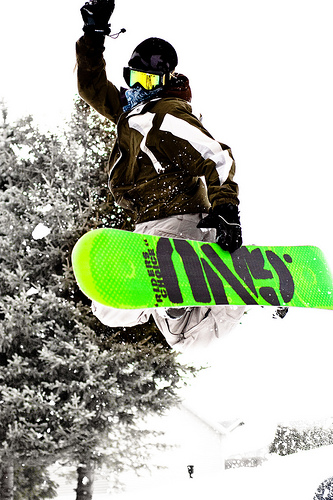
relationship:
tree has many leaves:
[1, 83, 223, 500] [2, 83, 193, 498]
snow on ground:
[107, 440, 332, 499] [52, 446, 331, 499]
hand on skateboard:
[204, 203, 243, 256] [70, 224, 333, 312]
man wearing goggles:
[54, 5, 292, 347] [119, 63, 171, 98]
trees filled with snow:
[1, 83, 223, 500] [107, 440, 332, 499]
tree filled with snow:
[1, 83, 223, 500] [107, 440, 332, 499]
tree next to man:
[1, 83, 223, 500] [54, 5, 292, 347]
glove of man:
[204, 203, 243, 256] [54, 5, 292, 347]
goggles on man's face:
[119, 63, 171, 98] [123, 59, 172, 96]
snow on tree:
[107, 440, 332, 499] [1, 83, 223, 500]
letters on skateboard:
[133, 226, 299, 309] [70, 224, 333, 312]